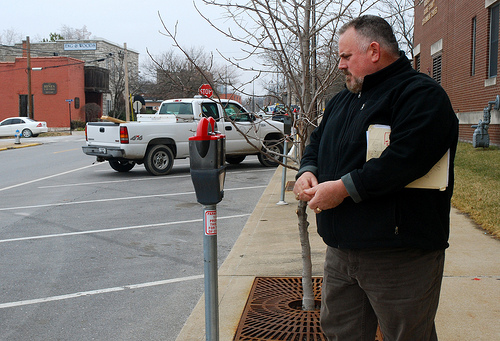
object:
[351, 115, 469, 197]
folder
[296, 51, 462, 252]
black jacket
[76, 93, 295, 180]
truck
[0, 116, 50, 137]
car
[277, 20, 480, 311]
man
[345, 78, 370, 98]
beard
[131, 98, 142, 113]
sign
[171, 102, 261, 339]
pole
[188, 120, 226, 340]
parking meter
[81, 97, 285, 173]
truck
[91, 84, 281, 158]
white truck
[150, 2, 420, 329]
tree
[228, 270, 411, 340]
gate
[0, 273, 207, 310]
line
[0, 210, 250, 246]
line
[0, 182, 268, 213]
line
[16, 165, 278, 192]
line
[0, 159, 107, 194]
line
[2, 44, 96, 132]
building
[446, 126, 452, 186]
paper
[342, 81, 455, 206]
arm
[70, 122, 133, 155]
tailgate truck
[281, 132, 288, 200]
pole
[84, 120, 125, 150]
tailgate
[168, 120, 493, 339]
sidewalk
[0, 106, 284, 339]
street